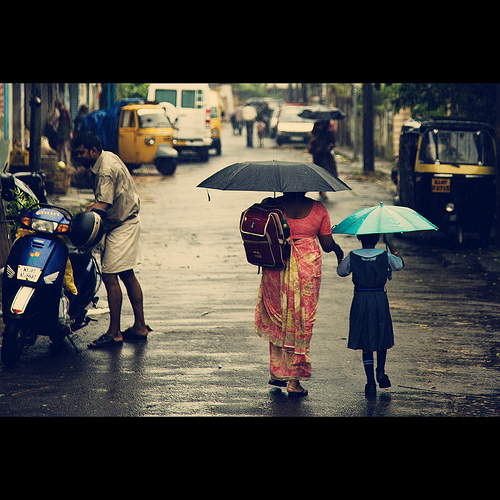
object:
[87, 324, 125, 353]
feet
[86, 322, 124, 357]
black sandals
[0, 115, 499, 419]
road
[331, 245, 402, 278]
shirt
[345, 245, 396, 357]
dress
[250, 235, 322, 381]
skirt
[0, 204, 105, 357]
scooter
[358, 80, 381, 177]
pole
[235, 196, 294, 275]
backpack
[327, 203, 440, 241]
umbrella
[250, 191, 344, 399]
person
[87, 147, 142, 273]
outfit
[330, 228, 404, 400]
girl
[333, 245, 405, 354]
uniform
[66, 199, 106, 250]
helmet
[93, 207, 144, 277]
shorts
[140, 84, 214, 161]
van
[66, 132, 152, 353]
man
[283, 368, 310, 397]
sandals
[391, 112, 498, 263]
taxi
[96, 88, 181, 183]
taxi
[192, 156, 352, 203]
black canopy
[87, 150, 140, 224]
shirt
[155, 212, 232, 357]
rain